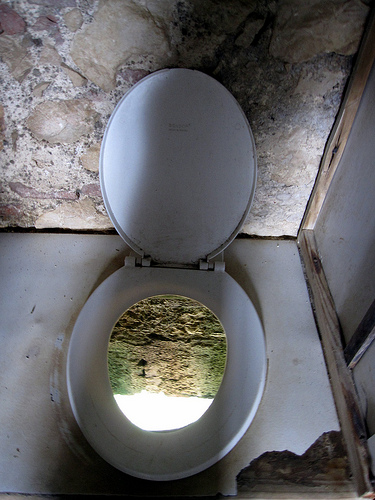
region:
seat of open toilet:
[52, 264, 271, 483]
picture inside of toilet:
[103, 286, 231, 433]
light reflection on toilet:
[231, 386, 262, 433]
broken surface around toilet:
[262, 430, 338, 488]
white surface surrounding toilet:
[42, 302, 82, 366]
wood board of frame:
[313, 262, 346, 363]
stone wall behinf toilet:
[31, 51, 133, 187]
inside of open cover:
[91, 65, 264, 262]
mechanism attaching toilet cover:
[110, 253, 233, 276]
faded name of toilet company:
[160, 115, 196, 142]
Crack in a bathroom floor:
[274, 429, 351, 485]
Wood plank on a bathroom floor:
[294, 227, 369, 486]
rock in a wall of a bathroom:
[64, 9, 172, 73]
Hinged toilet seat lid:
[119, 250, 227, 273]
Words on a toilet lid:
[167, 120, 193, 132]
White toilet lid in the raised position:
[87, 58, 267, 275]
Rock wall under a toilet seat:
[121, 309, 222, 390]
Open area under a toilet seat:
[113, 389, 211, 431]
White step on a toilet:
[5, 240, 67, 476]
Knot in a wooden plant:
[326, 132, 341, 171]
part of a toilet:
[176, 146, 215, 192]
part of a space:
[149, 388, 207, 451]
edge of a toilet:
[196, 459, 234, 470]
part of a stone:
[269, 432, 319, 483]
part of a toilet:
[197, 415, 236, 453]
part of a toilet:
[68, 432, 117, 485]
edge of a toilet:
[143, 436, 197, 488]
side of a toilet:
[138, 426, 181, 495]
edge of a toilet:
[190, 433, 229, 468]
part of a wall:
[258, 398, 296, 474]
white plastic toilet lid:
[87, 61, 267, 272]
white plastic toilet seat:
[59, 260, 273, 486]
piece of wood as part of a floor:
[235, 425, 353, 499]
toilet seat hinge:
[195, 255, 230, 272]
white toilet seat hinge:
[119, 253, 155, 271]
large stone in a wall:
[19, 90, 100, 151]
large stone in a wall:
[69, 0, 171, 98]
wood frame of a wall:
[287, 225, 373, 499]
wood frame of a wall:
[341, 297, 373, 378]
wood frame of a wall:
[291, 6, 370, 247]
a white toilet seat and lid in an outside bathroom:
[65, 84, 266, 482]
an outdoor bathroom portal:
[1, 16, 374, 498]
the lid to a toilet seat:
[100, 67, 256, 264]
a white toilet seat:
[64, 258, 267, 483]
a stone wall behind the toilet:
[8, 4, 352, 65]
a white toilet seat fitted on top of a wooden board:
[2, 236, 319, 499]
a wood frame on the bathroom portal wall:
[294, 125, 370, 487]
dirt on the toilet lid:
[103, 208, 247, 270]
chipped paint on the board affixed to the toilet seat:
[235, 431, 349, 497]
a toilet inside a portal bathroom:
[66, 68, 265, 483]